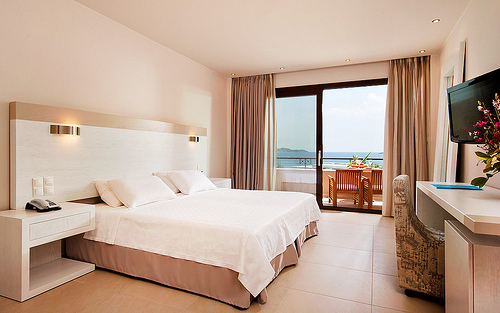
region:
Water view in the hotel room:
[280, 110, 395, 222]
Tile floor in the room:
[323, 239, 350, 263]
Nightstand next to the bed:
[19, 189, 107, 311]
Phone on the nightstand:
[21, 177, 81, 213]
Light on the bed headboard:
[26, 105, 156, 200]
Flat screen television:
[433, 75, 497, 134]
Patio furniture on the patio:
[317, 149, 417, 231]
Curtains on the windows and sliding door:
[236, 60, 494, 199]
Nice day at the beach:
[316, 97, 361, 136]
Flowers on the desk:
[467, 102, 494, 149]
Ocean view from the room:
[263, 80, 402, 237]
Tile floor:
[336, 257, 371, 295]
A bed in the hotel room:
[56, 129, 303, 311]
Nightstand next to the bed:
[16, 154, 96, 251]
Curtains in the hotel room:
[231, 90, 269, 175]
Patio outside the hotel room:
[310, 151, 405, 203]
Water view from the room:
[286, 145, 355, 173]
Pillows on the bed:
[108, 168, 174, 180]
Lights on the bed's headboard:
[45, 115, 131, 152]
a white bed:
[59, 124, 307, 301]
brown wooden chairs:
[314, 135, 395, 232]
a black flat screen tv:
[406, 55, 496, 160]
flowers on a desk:
[393, 83, 498, 255]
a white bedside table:
[4, 168, 99, 288]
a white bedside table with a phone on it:
[5, 173, 111, 300]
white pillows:
[88, 169, 252, 218]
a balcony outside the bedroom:
[226, 61, 453, 217]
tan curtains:
[222, 50, 462, 223]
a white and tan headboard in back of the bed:
[3, 84, 238, 233]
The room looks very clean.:
[3, 1, 496, 311]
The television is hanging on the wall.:
[441, 62, 498, 149]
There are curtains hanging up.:
[227, 50, 450, 217]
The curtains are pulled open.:
[232, 40, 443, 217]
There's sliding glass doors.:
[254, 79, 398, 218]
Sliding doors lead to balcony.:
[271, 148, 429, 219]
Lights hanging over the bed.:
[30, 126, 208, 151]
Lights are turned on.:
[36, 118, 208, 158]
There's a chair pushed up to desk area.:
[386, 163, 461, 302]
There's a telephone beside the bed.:
[17, 195, 59, 217]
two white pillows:
[92, 173, 185, 211]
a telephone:
[26, 194, 70, 220]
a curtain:
[231, 71, 277, 219]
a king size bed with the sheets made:
[71, 159, 342, 305]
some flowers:
[471, 90, 498, 180]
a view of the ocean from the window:
[267, 81, 383, 167]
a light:
[43, 110, 98, 142]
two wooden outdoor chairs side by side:
[324, 158, 405, 213]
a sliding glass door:
[313, 79, 417, 221]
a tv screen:
[438, 72, 498, 140]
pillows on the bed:
[97, 178, 173, 202]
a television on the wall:
[446, 84, 499, 136]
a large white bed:
[88, 183, 320, 289]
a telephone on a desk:
[25, 198, 60, 210]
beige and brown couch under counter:
[372, 165, 454, 310]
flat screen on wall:
[430, 60, 493, 153]